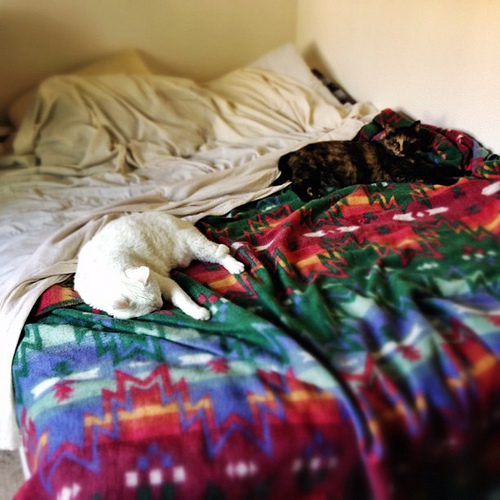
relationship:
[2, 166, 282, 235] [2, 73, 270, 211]
white bed sheets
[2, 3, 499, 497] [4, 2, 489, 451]
bed placed into corner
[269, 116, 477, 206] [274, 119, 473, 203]
tortie watches photographer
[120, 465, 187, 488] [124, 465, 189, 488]
three white blocks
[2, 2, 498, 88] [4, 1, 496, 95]
cream colored walls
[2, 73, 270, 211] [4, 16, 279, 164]
sheets match wall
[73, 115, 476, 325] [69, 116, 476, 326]
cats on bed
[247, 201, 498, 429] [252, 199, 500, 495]
multi colored blanket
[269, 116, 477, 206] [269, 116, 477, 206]
cat on bed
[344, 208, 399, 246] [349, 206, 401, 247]
pink on blanket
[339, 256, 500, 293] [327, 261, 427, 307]
gree on blanket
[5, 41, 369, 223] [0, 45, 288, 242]
un made bed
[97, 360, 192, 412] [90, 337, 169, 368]
stripe on blanket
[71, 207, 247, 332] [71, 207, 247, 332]
cat on bed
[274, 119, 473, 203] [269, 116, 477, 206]
brown and black cat fur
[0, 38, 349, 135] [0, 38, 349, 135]
pillows on bed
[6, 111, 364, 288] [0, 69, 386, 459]
pulled back sheets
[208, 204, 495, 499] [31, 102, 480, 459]
blanket on bed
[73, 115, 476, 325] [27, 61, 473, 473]
cats on bed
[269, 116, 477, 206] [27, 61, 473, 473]
cat on bed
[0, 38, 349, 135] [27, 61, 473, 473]
pillows on bed